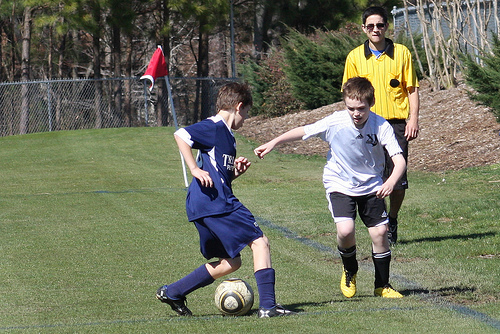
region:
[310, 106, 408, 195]
child wearing a white shirt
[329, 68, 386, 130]
child with brown hair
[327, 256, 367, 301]
child wearing yellow sneakers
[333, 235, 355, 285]
child wearing black socks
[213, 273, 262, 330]
child kicking a soccer ball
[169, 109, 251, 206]
child wearing blue shirt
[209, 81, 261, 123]
child with brown hair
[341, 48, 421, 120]
man wearing a yellow shirt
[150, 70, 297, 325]
A boy wearing blue shorts playing soccer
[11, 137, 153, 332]
A green grass soccerfield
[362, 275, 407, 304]
A boy's yellow shoe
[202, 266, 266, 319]
A black, yellow and white soccer ball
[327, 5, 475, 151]
A man wearing sunglasses and a yellow shirt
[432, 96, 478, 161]
A brown mulched hillside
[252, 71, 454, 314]
A boy wearing a white shirt playing soccer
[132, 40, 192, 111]
A red flag on a silver pole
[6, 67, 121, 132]
A silver metal chain link fence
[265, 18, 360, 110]
A green bush in the background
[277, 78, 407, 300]
boy wearing a white shirt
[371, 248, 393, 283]
black sock with a white stripe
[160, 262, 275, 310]
tall blue socks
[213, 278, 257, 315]
black and white soccer ball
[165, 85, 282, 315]
boy wearing a blue uniform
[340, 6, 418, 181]
referee wearing a yellow shirt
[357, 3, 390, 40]
man wearing sunglasses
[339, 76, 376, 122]
boy with short brown hair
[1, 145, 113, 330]
nicely trimmed field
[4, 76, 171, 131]
metal fence around the field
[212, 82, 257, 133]
head of a person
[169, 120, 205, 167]
arm of a person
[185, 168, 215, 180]
hand of a person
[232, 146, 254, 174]
hand of a person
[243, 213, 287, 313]
leg of a person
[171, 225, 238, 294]
leg of a person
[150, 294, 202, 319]
feet of a person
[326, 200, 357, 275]
leg of a person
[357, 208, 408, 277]
leg of a person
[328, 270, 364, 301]
feet of a person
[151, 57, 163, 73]
A red flag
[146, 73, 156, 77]
A red flag with white edge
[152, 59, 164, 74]
A soccer corner flag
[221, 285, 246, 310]
A soccer ball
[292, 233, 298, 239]
A blue line on the grass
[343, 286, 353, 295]
Yellow soccer boots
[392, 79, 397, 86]
A black badge on the shirt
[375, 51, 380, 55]
A blue t-shirt sticking out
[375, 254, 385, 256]
White stripes on the sock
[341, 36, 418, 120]
the shirt is yellow